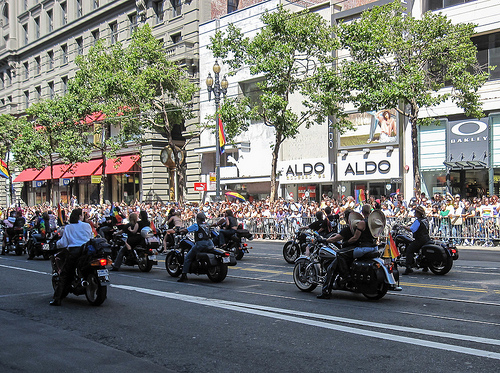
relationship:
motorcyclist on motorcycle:
[46, 209, 98, 309] [46, 232, 111, 307]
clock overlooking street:
[157, 142, 183, 168] [1, 236, 499, 371]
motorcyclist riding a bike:
[46, 209, 98, 309] [47, 230, 113, 307]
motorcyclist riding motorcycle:
[46, 209, 98, 309] [43, 237, 110, 306]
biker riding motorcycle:
[167, 212, 220, 280] [163, 233, 235, 285]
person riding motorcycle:
[305, 209, 329, 237] [291, 226, 403, 299]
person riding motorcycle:
[321, 202, 379, 300] [386, 224, 458, 278]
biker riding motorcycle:
[392, 208, 429, 276] [281, 225, 311, 260]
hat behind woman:
[368, 209, 385, 237] [334, 203, 376, 283]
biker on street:
[392, 208, 429, 276] [1, 250, 498, 371]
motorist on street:
[163, 213, 233, 283] [1, 250, 498, 371]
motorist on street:
[26, 213, 53, 258] [1, 250, 498, 371]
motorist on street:
[106, 214, 156, 269] [1, 250, 498, 371]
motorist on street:
[53, 209, 112, 306] [1, 250, 498, 371]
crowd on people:
[0, 193, 496, 245] [6, 196, 484, 235]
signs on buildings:
[274, 149, 401, 185] [6, 0, 416, 193]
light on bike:
[209, 245, 236, 267] [164, 228, 229, 282]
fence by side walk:
[242, 215, 498, 240] [230, 226, 473, 256]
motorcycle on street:
[107, 231, 157, 271] [0, 237, 480, 357]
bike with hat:
[51, 247, 124, 304] [367, 209, 385, 239]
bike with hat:
[163, 240, 212, 268] [345, 212, 366, 236]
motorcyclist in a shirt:
[46, 209, 98, 309] [42, 216, 93, 251]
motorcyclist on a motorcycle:
[46, 209, 98, 309] [36, 224, 126, 304]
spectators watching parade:
[234, 191, 302, 217] [10, 195, 460, 336]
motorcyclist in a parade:
[166, 230, 238, 282] [0, 170, 457, 322]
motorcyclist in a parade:
[294, 235, 401, 301] [0, 170, 457, 322]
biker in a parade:
[167, 212, 220, 280] [0, 170, 457, 322]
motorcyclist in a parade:
[62, 223, 194, 298] [52, 204, 472, 325]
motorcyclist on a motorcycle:
[107, 213, 139, 273] [106, 223, 163, 272]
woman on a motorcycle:
[334, 203, 376, 283] [291, 226, 403, 299]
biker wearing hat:
[392, 208, 429, 276] [341, 206, 372, 237]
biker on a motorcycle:
[392, 208, 429, 276] [282, 229, 412, 301]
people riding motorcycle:
[161, 204, 446, 309] [0, 202, 470, 311]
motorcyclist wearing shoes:
[46, 209, 98, 309] [39, 292, 69, 312]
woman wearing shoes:
[129, 207, 150, 245] [39, 292, 69, 312]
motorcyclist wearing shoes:
[107, 213, 139, 273] [39, 292, 69, 312]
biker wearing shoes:
[392, 208, 429, 276] [39, 292, 69, 312]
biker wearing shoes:
[167, 212, 220, 280] [39, 292, 69, 312]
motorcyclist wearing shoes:
[46, 209, 98, 309] [43, 288, 68, 313]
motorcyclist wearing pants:
[46, 209, 98, 309] [44, 238, 134, 330]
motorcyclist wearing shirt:
[46, 209, 98, 309] [63, 223, 89, 248]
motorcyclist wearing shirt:
[46, 209, 98, 309] [54, 222, 96, 253]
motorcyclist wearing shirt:
[46, 209, 98, 309] [52, 223, 97, 245]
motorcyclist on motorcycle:
[46, 209, 98, 309] [212, 227, 245, 262]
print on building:
[335, 111, 397, 146] [196, 0, 413, 210]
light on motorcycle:
[96, 256, 106, 269] [41, 232, 108, 304]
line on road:
[0, 262, 218, 307] [1, 240, 498, 371]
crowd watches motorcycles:
[0, 193, 496, 245] [0, 200, 463, 305]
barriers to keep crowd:
[148, 216, 496, 237] [0, 193, 496, 245]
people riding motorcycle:
[45, 180, 460, 346] [285, 228, 404, 306]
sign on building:
[273, 144, 435, 196] [63, 10, 455, 266]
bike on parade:
[47, 230, 113, 307] [2, 201, 498, 324]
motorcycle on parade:
[291, 226, 403, 299] [2, 201, 498, 324]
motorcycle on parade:
[386, 224, 458, 278] [2, 201, 498, 324]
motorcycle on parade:
[107, 231, 157, 271] [2, 201, 498, 324]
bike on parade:
[164, 228, 229, 282] [2, 201, 498, 324]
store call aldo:
[339, 146, 399, 202] [345, 159, 390, 174]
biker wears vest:
[389, 219, 482, 283] [410, 212, 435, 239]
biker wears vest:
[177, 205, 231, 280] [185, 221, 239, 251]